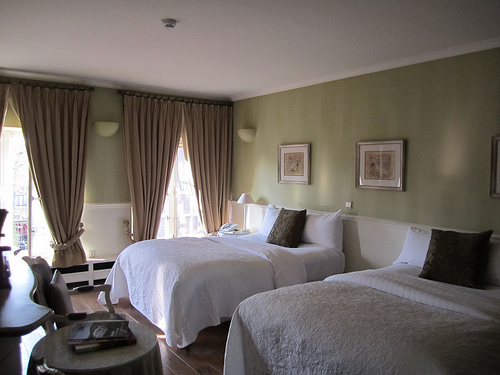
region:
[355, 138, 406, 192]
framed artwork on the wall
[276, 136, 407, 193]
two pictures hanging next to each other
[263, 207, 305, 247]
a brown throw pillows on the bed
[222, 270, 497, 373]
the bed spread is white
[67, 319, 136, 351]
a stack of books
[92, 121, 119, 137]
a light fixture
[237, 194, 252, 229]
a small table lamp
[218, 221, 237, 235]
phone on the night stand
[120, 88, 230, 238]
tan window curtains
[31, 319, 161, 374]
a round end table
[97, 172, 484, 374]
beds in a bedroom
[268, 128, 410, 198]
framed pictures on a wall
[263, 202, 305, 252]
pillow on a bed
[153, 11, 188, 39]
sprinkler on the ceiling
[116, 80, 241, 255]
curtains on a window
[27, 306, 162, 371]
table in hotel room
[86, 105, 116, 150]
light sconce on a wall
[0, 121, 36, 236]
sun shining through the windows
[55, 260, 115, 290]
radiator on the floor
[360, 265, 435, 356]
comforter on the bed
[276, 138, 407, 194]
Two pictures over the beds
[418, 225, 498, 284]
Black pillow on the bed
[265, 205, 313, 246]
Pillow on the bed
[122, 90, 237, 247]
Draperies over the window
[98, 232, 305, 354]
White quilt on bed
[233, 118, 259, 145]
Lamp on the wall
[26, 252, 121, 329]
Chair across from bed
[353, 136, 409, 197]
Picture on the wall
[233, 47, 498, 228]
Wall painted green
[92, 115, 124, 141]
Lamp on the wall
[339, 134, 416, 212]
a picture frame on the wall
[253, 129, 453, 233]
two picture frames on the wall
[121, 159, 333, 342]
a bed with pillows on it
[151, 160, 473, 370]
two beds with pillows on it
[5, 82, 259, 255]
curtains hanging on the windows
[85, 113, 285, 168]
lights hanging on the wall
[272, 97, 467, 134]
green walls in a bedroom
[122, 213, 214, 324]
white comforter on a bed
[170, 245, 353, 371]
white comforters on two beds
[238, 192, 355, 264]
white pillows on a bed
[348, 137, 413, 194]
picture in a brown frame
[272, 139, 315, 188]
picture in a brown frame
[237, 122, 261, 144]
wall sconce with white shade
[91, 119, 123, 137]
wall sconce with white shade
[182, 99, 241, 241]
brown curtain hanging in front of window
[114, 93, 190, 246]
brown curtain hanging in front of window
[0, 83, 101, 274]
brown curtain hanging in front of window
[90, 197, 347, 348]
bed with white linens on it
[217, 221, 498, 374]
bed with white linens on it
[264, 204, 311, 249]
brown throw pillow on the white bed